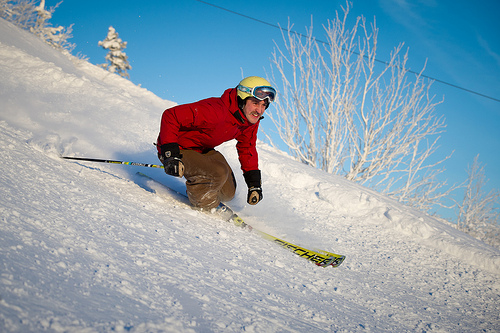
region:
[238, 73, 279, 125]
the head of a man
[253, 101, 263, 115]
the nose of a man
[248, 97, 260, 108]
the eye of a man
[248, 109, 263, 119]
the mouth of a man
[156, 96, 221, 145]
the arm of a man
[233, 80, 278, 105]
a pair of goggles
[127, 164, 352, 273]
a pair of skis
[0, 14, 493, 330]
white snow on the ground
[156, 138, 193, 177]
a black glove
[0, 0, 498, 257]
a clear blue sky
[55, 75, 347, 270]
person is skiing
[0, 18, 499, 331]
the snow is white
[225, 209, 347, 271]
skis are yellow and black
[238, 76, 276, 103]
person is wearing helmet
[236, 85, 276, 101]
helmet has ski goggles on it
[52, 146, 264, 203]
person is holding ski poles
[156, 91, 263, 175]
The coat is red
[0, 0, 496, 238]
the sky is blue and clear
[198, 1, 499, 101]
black cord hanging above slope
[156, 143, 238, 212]
person is wearing brown pants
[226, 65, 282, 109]
bright yellow ski helmet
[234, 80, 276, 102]
bright blue ski goggles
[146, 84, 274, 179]
thick red snow jacket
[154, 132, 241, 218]
thick tan snow pants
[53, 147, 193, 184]
long black ski pole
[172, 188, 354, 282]
bright yellow pair of skis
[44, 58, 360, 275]
man skiing down snowy hill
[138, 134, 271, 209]
thick black snow gloves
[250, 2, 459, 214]
bare tree covered in ice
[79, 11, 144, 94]
pine tree covered in snow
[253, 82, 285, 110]
ski goggles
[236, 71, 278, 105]
a yellow ski helmet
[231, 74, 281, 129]
the face of a man skiing downhill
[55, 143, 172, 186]
a ski pole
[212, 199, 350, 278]
two skis on snow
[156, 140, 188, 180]
a skiing glove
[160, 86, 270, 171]
a red winter jacket won by a skier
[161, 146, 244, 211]
brown snow pants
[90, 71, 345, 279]
a man skiing downhill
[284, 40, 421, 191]
a snow-covered tree on a ski hill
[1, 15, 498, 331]
The hillside is covered in snow.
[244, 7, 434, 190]
The tree is bare.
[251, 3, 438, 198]
The tree is leafless.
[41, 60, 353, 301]
The man is skiing.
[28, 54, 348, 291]
The man is crouched down.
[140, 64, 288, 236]
The man is wearing a helmet.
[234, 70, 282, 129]
The helmet is yellow.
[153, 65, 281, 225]
The man is wearing gloves.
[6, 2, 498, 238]
The sky is blue.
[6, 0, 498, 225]
The sky is cloudless.